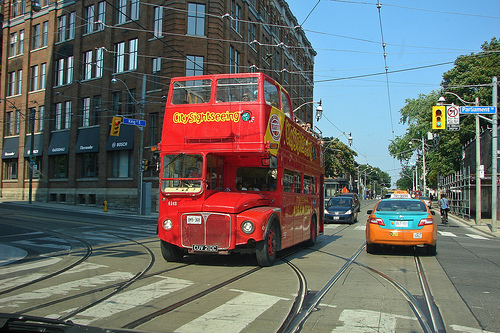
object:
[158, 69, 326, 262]
bus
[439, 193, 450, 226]
person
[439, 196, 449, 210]
shirt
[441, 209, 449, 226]
bike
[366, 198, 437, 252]
taxi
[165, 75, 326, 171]
deck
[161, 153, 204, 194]
front window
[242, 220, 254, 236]
headlights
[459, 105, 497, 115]
street sign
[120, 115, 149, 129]
street sign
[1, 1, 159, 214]
building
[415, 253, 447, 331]
tracks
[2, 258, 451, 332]
street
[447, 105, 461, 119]
an arrow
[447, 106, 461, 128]
street sign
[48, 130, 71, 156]
canopy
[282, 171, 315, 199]
side windows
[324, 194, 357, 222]
car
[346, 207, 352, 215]
headlights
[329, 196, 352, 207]
window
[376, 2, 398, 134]
wires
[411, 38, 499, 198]
trees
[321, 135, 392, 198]
trees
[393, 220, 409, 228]
license plate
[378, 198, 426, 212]
back window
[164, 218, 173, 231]
headlight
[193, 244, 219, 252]
license plate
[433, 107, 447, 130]
light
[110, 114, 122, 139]
light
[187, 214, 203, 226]
license plate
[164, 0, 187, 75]
bricks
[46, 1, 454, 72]
wires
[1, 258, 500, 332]
crosswalk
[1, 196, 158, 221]
sidewalk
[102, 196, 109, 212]
fire hydrant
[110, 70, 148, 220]
streetlight